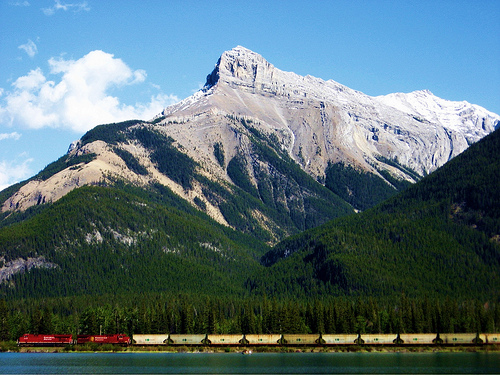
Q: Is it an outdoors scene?
A: Yes, it is outdoors.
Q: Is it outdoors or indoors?
A: It is outdoors.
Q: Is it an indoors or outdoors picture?
A: It is outdoors.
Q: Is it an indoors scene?
A: No, it is outdoors.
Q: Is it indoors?
A: No, it is outdoors.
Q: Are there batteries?
A: No, there are no batteries.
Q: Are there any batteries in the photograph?
A: No, there are no batteries.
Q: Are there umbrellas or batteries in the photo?
A: No, there are no batteries or umbrellas.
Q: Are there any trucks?
A: No, there are no trucks.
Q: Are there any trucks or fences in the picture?
A: No, there are no trucks or fences.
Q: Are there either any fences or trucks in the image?
A: No, there are no trucks or fences.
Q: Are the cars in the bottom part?
A: Yes, the cars are in the bottom of the image.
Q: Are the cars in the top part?
A: No, the cars are in the bottom of the image.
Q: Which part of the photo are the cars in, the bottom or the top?
A: The cars are in the bottom of the image.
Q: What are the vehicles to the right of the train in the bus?
A: The vehicles are cars.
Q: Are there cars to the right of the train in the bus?
A: Yes, there are cars to the right of the train.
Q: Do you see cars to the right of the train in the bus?
A: Yes, there are cars to the right of the train.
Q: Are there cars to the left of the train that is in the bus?
A: No, the cars are to the right of the train.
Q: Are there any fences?
A: No, there are no fences.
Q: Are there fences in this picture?
A: No, there are no fences.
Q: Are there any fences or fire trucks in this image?
A: No, there are no fences or fire trucks.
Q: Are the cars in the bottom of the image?
A: Yes, the cars are in the bottom of the image.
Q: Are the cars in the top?
A: No, the cars are in the bottom of the image.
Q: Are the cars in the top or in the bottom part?
A: The cars are in the bottom of the image.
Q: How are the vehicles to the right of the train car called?
A: The vehicles are cars.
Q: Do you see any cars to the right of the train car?
A: Yes, there are cars to the right of the train car.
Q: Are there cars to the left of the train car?
A: No, the cars are to the right of the train car.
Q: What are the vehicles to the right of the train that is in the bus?
A: The vehicles are cars.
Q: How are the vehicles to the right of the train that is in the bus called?
A: The vehicles are cars.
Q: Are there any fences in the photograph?
A: No, there are no fences.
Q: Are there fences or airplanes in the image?
A: No, there are no fences or airplanes.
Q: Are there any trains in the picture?
A: Yes, there is a train.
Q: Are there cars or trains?
A: Yes, there is a train.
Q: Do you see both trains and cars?
A: Yes, there are both a train and cars.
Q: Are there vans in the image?
A: No, there are no vans.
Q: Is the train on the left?
A: Yes, the train is on the left of the image.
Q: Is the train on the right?
A: No, the train is on the left of the image.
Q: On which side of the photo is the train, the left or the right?
A: The train is on the left of the image.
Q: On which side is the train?
A: The train is on the left of the image.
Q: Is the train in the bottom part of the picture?
A: Yes, the train is in the bottom of the image.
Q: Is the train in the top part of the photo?
A: No, the train is in the bottom of the image.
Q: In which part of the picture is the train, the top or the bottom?
A: The train is in the bottom of the image.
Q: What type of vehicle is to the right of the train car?
A: The vehicle is a train.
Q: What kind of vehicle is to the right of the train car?
A: The vehicle is a train.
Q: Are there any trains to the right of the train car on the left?
A: Yes, there is a train to the right of the train car.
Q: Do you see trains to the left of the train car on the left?
A: No, the train is to the right of the train car.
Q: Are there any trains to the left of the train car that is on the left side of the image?
A: No, the train is to the right of the train car.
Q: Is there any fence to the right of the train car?
A: No, there is a train to the right of the train car.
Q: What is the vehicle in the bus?
A: The vehicle is a train.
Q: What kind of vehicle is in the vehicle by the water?
A: The vehicle is a train.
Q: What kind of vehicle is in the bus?
A: The vehicle is a train.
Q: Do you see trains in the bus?
A: Yes, there is a train in the bus.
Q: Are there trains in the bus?
A: Yes, there is a train in the bus.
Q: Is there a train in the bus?
A: Yes, there is a train in the bus.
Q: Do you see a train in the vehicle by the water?
A: Yes, there is a train in the bus.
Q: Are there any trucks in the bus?
A: No, there is a train in the bus.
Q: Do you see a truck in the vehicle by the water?
A: No, there is a train in the bus.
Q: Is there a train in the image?
A: Yes, there is a train.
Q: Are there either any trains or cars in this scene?
A: Yes, there is a train.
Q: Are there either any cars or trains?
A: Yes, there is a train.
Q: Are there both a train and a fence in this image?
A: No, there is a train but no fences.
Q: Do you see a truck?
A: No, there are no trucks.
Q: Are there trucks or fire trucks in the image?
A: No, there are no trucks or fire trucks.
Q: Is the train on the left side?
A: Yes, the train is on the left of the image.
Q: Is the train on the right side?
A: No, the train is on the left of the image.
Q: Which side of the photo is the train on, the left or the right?
A: The train is on the left of the image.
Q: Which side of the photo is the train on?
A: The train is on the left of the image.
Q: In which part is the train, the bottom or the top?
A: The train is in the bottom of the image.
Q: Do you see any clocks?
A: No, there are no clocks.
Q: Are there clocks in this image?
A: No, there are no clocks.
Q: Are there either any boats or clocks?
A: No, there are no clocks or boats.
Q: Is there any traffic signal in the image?
A: No, there are no traffic lights.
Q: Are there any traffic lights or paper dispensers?
A: No, there are no traffic lights or paper dispensers.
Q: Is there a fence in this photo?
A: No, there are no fences.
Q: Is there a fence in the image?
A: No, there are no fences.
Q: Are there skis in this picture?
A: No, there are no skis.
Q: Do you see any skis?
A: No, there are no skis.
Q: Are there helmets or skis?
A: No, there are no skis or helmets.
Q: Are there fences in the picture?
A: No, there are no fences.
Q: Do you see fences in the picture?
A: No, there are no fences.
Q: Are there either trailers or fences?
A: No, there are no fences or trailers.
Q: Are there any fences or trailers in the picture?
A: No, there are no fences or trailers.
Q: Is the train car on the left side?
A: Yes, the train car is on the left of the image.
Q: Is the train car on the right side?
A: No, the train car is on the left of the image.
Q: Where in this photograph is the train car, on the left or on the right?
A: The train car is on the left of the image.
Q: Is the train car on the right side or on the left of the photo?
A: The train car is on the left of the image.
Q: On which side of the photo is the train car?
A: The train car is on the left of the image.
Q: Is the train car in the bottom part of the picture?
A: Yes, the train car is in the bottom of the image.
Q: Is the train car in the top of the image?
A: No, the train car is in the bottom of the image.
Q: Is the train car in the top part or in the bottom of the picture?
A: The train car is in the bottom of the image.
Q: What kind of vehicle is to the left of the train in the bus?
A: The vehicle is a train car.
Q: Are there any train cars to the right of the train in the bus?
A: No, the train car is to the left of the train.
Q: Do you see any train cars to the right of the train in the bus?
A: No, the train car is to the left of the train.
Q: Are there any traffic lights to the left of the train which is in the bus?
A: No, there is a train car to the left of the train.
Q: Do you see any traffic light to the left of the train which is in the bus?
A: No, there is a train car to the left of the train.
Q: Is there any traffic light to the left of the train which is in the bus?
A: No, there is a train car to the left of the train.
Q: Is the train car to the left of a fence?
A: No, the train car is to the left of the train.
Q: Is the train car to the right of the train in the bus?
A: No, the train car is to the left of the train.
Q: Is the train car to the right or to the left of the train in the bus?
A: The train car is to the left of the train.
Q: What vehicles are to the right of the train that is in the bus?
A: The vehicles are cars.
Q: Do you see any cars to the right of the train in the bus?
A: Yes, there are cars to the right of the train.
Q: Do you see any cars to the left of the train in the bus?
A: No, the cars are to the right of the train.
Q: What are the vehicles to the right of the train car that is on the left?
A: The vehicles are cars.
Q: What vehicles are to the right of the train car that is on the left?
A: The vehicles are cars.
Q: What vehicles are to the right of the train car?
A: The vehicles are cars.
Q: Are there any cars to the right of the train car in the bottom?
A: Yes, there are cars to the right of the train car.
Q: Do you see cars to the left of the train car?
A: No, the cars are to the right of the train car.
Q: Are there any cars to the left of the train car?
A: No, the cars are to the right of the train car.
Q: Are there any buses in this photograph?
A: Yes, there is a bus.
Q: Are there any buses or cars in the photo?
A: Yes, there is a bus.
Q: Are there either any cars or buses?
A: Yes, there is a bus.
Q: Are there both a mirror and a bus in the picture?
A: No, there is a bus but no mirrors.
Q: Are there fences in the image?
A: No, there are no fences.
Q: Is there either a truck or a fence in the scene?
A: No, there are no fences or trucks.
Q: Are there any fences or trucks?
A: No, there are no fences or trucks.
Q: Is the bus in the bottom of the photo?
A: Yes, the bus is in the bottom of the image.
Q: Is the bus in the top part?
A: No, the bus is in the bottom of the image.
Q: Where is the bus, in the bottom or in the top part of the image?
A: The bus is in the bottom of the image.